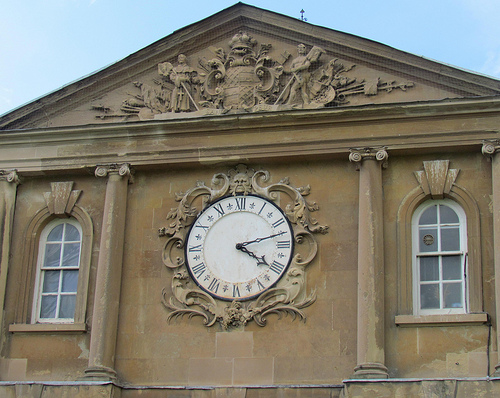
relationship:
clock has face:
[180, 191, 300, 301] [203, 211, 278, 286]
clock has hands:
[180, 191, 300, 301] [232, 230, 288, 269]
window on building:
[6, 156, 491, 334] [0, 1, 500, 396]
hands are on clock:
[232, 230, 288, 269] [180, 191, 300, 301]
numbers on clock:
[187, 196, 298, 304] [180, 191, 300, 301]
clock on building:
[180, 191, 300, 301] [0, 1, 500, 396]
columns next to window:
[92, 157, 404, 384] [6, 156, 491, 334]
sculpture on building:
[141, 29, 383, 110] [0, 1, 500, 396]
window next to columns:
[6, 156, 491, 334] [92, 157, 404, 384]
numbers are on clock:
[187, 196, 298, 304] [180, 191, 300, 301]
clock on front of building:
[180, 191, 300, 301] [0, 1, 500, 396]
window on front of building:
[6, 156, 491, 334] [0, 1, 500, 396]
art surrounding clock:
[144, 166, 335, 333] [180, 191, 300, 301]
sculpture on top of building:
[141, 29, 383, 110] [0, 1, 500, 396]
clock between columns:
[180, 191, 300, 301] [92, 157, 404, 384]